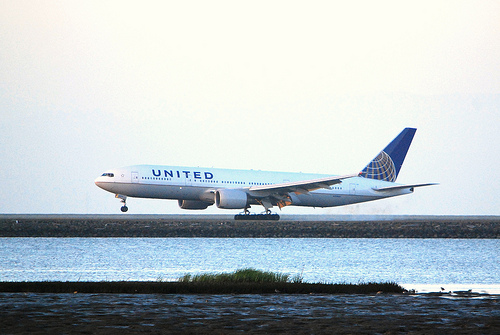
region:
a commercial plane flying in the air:
[87, 111, 471, 246]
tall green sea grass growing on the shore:
[173, 269, 308, 294]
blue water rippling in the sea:
[387, 246, 454, 281]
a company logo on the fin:
[367, 152, 399, 184]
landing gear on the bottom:
[111, 206, 292, 225]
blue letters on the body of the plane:
[151, 162, 218, 181]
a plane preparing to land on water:
[55, 126, 494, 303]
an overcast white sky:
[200, 54, 391, 121]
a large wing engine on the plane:
[204, 186, 254, 210]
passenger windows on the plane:
[145, 174, 214, 185]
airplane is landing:
[96, 127, 441, 219]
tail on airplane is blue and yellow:
[356, 126, 417, 182]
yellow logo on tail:
[358, 149, 398, 182]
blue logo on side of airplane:
[152, 168, 212, 179]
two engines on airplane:
[178, 187, 249, 209]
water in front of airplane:
[0, 236, 499, 295]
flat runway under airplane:
[0, 213, 499, 220]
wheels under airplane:
[121, 205, 279, 220]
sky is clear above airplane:
[0, 1, 499, 215]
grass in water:
[154, 267, 410, 294]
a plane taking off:
[31, 83, 477, 313]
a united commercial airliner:
[65, 81, 448, 273]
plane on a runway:
[37, 60, 468, 305]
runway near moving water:
[8, 208, 491, 301]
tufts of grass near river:
[135, 240, 311, 319]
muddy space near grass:
[211, 282, 480, 329]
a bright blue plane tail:
[348, 91, 435, 205]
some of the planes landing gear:
[223, 198, 289, 220]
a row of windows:
[177, 170, 285, 192]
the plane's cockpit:
[86, 165, 139, 202]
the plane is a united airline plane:
[106, 130, 443, 225]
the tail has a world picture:
[353, 146, 405, 179]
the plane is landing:
[88, 128, 436, 235]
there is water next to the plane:
[47, 235, 490, 297]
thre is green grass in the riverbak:
[181, 260, 381, 291]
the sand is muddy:
[124, 296, 316, 333]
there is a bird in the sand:
[425, 280, 450, 293]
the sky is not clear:
[38, 84, 499, 121]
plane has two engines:
[63, 134, 438, 239]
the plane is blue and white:
[78, 118, 464, 231]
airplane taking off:
[91, 126, 441, 223]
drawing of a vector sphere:
[357, 147, 397, 183]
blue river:
[0, 234, 499, 281]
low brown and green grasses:
[0, 266, 417, 295]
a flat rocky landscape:
[1, 213, 498, 238]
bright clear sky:
[1, 2, 498, 124]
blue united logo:
[148, 165, 215, 182]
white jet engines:
[175, 186, 250, 211]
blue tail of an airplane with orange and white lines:
[355, 124, 417, 181]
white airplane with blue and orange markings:
[90, 118, 441, 228]